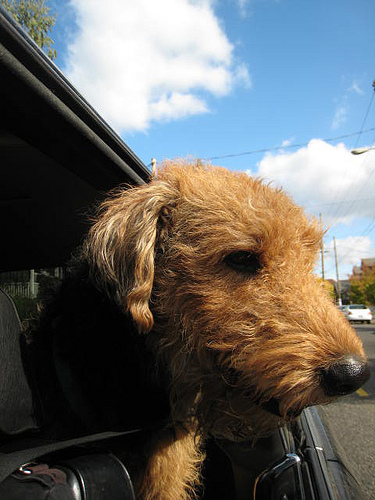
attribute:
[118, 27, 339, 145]
sky — blue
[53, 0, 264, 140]
clouds — white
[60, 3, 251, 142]
cloud — white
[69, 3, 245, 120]
clouds — white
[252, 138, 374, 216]
clouds — white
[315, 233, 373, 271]
clouds — white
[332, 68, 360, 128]
clouds — white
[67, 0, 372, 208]
sky — blue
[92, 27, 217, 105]
clouds — white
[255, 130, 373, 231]
cloud — white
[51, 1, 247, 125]
cloud — white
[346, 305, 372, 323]
car — white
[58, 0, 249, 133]
clouds — white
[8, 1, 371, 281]
sky — blue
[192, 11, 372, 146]
sky — blue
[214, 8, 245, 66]
clouds — white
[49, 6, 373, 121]
sky — blue